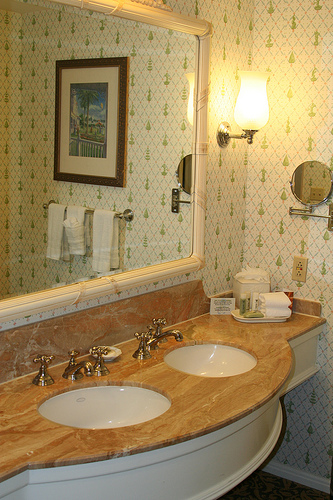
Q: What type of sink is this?
A: Double.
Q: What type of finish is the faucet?
A: Chrome.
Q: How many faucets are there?
A: 2.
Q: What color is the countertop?
A: Brown.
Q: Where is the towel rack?
A: On the same wall as the circular mirror.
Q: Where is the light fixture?
A: Adjacent to the mirror above the vanity.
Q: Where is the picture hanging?
A: Above the towel rack and adjacent to the circular mirror.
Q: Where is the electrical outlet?
A: Below the circular mirror.